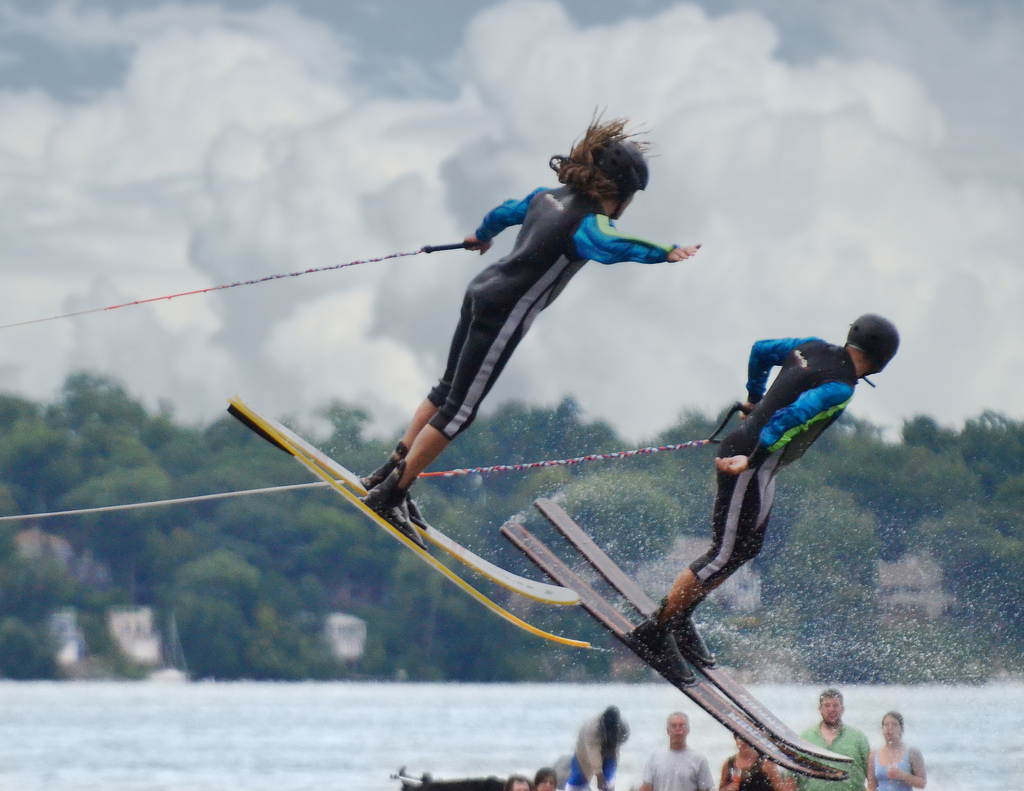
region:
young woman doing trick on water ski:
[264, 106, 737, 455]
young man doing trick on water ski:
[639, 296, 911, 698]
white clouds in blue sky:
[105, 78, 173, 135]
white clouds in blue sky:
[193, 68, 254, 120]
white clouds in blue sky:
[623, 337, 665, 385]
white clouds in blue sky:
[925, 148, 999, 234]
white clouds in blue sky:
[228, 186, 287, 243]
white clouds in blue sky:
[79, 188, 153, 247]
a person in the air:
[216, 96, 710, 692]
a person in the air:
[624, 291, 928, 691]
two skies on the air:
[492, 478, 860, 782]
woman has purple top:
[860, 696, 925, 782]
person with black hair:
[340, 85, 724, 572]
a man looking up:
[625, 691, 717, 787]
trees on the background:
[15, 368, 1022, 724]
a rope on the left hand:
[8, 99, 724, 381]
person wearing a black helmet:
[571, 126, 661, 210]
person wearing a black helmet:
[850, 309, 898, 371]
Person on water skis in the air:
[208, 382, 623, 662]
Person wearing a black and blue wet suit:
[433, 176, 662, 434]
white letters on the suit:
[537, 180, 569, 215]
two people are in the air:
[172, 42, 980, 783]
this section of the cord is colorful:
[399, 407, 766, 550]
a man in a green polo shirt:
[784, 647, 886, 787]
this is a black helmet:
[808, 278, 914, 381]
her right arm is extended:
[210, 85, 722, 616]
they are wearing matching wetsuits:
[393, 56, 953, 679]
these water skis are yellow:
[178, 351, 621, 715]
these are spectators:
[536, 680, 942, 788]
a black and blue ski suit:
[425, 180, 666, 436]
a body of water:
[0, 660, 1021, 787]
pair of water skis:
[495, 462, 878, 785]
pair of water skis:
[495, 470, 860, 777]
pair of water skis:
[493, 478, 871, 773]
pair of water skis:
[486, 467, 885, 785]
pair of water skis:
[474, 455, 866, 768]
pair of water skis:
[498, 473, 868, 777]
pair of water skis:
[486, 478, 910, 783]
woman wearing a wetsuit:
[404, 164, 602, 444]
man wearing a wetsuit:
[691, 318, 816, 581]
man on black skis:
[502, 478, 850, 788]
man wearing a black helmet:
[838, 304, 897, 372]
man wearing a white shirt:
[637, 743, 699, 783]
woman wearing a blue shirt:
[863, 739, 922, 787]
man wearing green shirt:
[800, 676, 868, 778]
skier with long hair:
[192, 109, 673, 666]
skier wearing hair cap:
[519, 316, 900, 775]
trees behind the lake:
[6, 377, 1018, 673]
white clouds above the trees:
[12, 16, 1014, 416]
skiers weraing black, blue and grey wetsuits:
[360, 128, 905, 650]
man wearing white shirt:
[635, 699, 709, 788]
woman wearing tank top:
[866, 705, 930, 788]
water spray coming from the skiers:
[476, 382, 989, 750]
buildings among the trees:
[10, 519, 988, 675]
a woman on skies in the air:
[210, 114, 710, 652]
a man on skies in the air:
[510, 307, 900, 775]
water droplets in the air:
[782, 486, 1017, 682]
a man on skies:
[556, 300, 981, 658]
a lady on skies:
[202, 78, 715, 590]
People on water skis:
[310, 86, 905, 738]